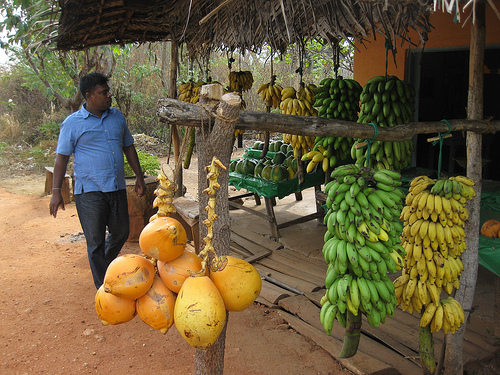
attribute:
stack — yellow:
[399, 165, 475, 341]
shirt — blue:
[52, 104, 139, 202]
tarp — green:
[224, 171, 325, 198]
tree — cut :
[181, 83, 250, 370]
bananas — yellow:
[402, 172, 469, 331]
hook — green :
[434, 123, 447, 183]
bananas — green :
[320, 141, 405, 325]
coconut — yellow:
[173, 273, 225, 346]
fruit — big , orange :
[136, 217, 192, 259]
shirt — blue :
[60, 102, 127, 191]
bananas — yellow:
[404, 169, 457, 349]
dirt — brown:
[33, 290, 87, 358]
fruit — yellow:
[168, 271, 229, 352]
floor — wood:
[243, 217, 325, 296]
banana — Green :
[349, 183, 362, 199]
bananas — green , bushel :
[313, 165, 392, 325]